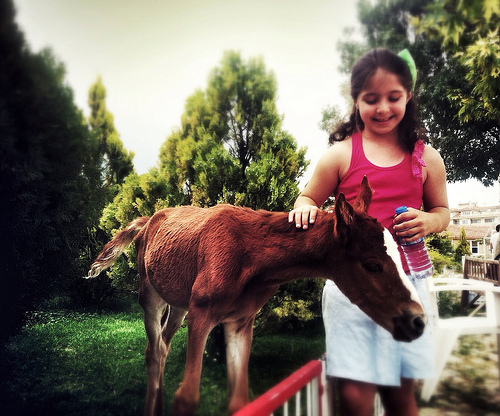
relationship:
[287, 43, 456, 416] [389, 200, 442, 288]
girl holding water bottle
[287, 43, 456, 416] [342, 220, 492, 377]
girl with shorts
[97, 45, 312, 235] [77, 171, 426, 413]
green tree behind pony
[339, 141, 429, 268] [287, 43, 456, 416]
top worn by girl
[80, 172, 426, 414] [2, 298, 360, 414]
horse in yard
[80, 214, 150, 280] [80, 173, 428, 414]
tail on horse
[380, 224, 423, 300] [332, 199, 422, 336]
patch on horse's face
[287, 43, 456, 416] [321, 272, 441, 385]
girl wearing shorts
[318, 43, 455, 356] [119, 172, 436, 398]
girl petting horse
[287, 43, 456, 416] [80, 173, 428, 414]
girl petting horse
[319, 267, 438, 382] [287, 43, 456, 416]
skirt worn by girl